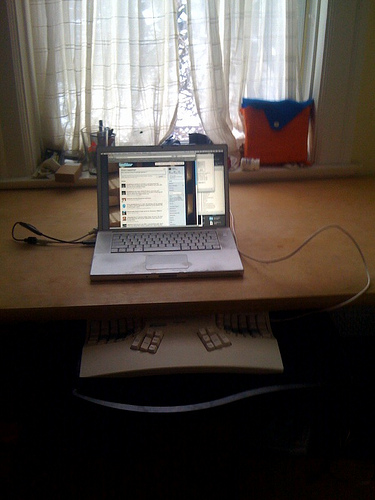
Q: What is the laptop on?
A: A desk.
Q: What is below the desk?
A: A keyboard.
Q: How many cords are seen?
A: 2.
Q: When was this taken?
A: Daytime.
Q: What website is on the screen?
A: Twitter.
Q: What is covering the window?
A: A curtain.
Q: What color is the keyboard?
A: Tan.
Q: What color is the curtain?
A: White.